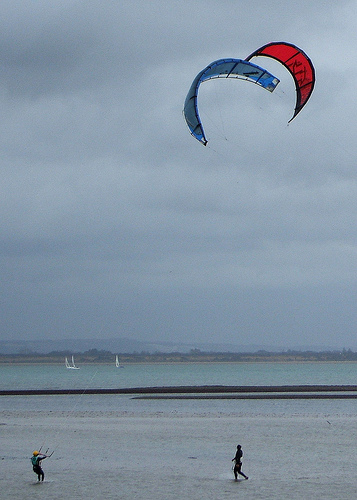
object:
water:
[0, 362, 356, 391]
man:
[231, 443, 247, 480]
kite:
[184, 56, 280, 145]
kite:
[242, 39, 314, 123]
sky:
[0, 0, 355, 354]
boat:
[115, 354, 124, 369]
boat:
[69, 352, 80, 370]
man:
[27, 449, 54, 481]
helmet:
[33, 448, 38, 456]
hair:
[237, 443, 241, 447]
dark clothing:
[230, 450, 248, 477]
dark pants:
[233, 462, 246, 480]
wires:
[52, 155, 232, 442]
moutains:
[0, 348, 356, 363]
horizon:
[0, 0, 356, 365]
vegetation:
[53, 349, 112, 357]